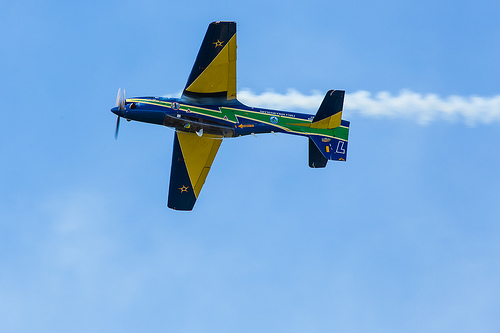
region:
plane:
[91, 22, 383, 233]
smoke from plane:
[365, 65, 455, 147]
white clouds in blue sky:
[45, 219, 77, 263]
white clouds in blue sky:
[351, 235, 398, 283]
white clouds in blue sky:
[267, 232, 291, 289]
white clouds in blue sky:
[90, 246, 181, 318]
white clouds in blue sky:
[265, 258, 309, 292]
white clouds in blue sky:
[378, 223, 449, 301]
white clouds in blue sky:
[22, 25, 73, 69]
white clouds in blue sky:
[71, 126, 118, 207]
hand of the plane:
[155, 20, 282, 85]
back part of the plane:
[268, 83, 367, 170]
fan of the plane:
[97, 75, 132, 161]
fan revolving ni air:
[112, 80, 137, 165]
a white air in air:
[260, 81, 495, 138]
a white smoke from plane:
[254, 78, 486, 125]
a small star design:
[170, 170, 194, 195]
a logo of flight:
[211, 35, 231, 51]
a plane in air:
[30, 28, 481, 313]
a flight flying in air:
[69, 21, 396, 233]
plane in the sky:
[103, 18, 351, 211]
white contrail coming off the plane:
[237, 80, 497, 130]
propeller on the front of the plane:
[100, 80, 137, 132]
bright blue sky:
[0, 1, 495, 326]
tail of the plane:
[297, 85, 359, 175]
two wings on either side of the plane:
[162, 10, 237, 210]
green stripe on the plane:
[130, 91, 355, 141]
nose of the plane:
[98, 79, 135, 134]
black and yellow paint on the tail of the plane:
[308, 83, 351, 130]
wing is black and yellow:
[162, 129, 226, 211]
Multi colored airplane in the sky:
[87, 21, 376, 213]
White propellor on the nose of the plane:
[98, 68, 138, 148]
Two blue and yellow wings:
[304, 85, 349, 185]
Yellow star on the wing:
[209, 36, 229, 58]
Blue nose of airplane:
[103, 86, 142, 126]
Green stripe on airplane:
[122, 83, 359, 159]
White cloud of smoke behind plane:
[207, 64, 499, 138]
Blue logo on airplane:
[264, 111, 281, 131]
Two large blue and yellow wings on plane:
[164, 16, 253, 248]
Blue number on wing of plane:
[335, 132, 347, 160]